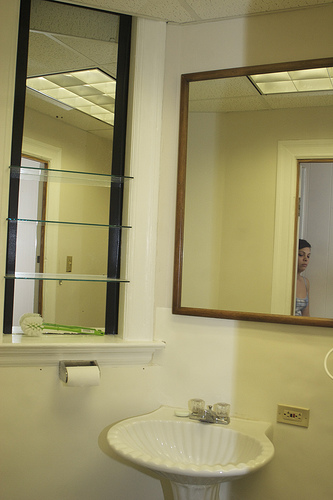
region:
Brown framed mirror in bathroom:
[171, 57, 332, 327]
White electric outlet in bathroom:
[275, 400, 311, 431]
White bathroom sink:
[104, 399, 272, 498]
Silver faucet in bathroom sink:
[199, 403, 218, 426]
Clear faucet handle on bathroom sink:
[215, 399, 232, 418]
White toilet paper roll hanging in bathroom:
[59, 362, 103, 388]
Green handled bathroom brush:
[15, 311, 106, 335]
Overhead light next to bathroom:
[26, 63, 115, 128]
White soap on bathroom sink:
[171, 403, 190, 420]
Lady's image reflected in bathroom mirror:
[291, 238, 313, 317]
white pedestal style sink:
[99, 396, 275, 499]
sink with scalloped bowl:
[102, 394, 275, 477]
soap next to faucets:
[173, 407, 191, 417]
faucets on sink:
[188, 398, 231, 427]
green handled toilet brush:
[20, 312, 103, 339]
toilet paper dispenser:
[55, 360, 104, 386]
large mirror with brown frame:
[177, 72, 331, 326]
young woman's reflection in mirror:
[295, 239, 313, 317]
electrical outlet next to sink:
[273, 400, 311, 429]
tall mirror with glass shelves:
[19, 2, 123, 331]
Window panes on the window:
[6, 164, 136, 288]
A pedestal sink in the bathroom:
[109, 406, 276, 497]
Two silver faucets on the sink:
[188, 395, 231, 424]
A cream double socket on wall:
[278, 403, 311, 427]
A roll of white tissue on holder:
[65, 366, 101, 385]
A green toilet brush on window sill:
[19, 313, 108, 337]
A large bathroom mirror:
[172, 66, 326, 325]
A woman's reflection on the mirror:
[297, 237, 312, 318]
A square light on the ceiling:
[26, 68, 114, 120]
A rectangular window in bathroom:
[2, 3, 127, 346]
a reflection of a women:
[288, 235, 318, 323]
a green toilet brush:
[13, 311, 115, 338]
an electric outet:
[271, 401, 316, 430]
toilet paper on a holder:
[57, 358, 116, 390]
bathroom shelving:
[7, 158, 134, 295]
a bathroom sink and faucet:
[104, 398, 277, 497]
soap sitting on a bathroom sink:
[171, 405, 192, 422]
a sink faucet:
[186, 395, 238, 427]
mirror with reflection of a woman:
[182, 74, 332, 324]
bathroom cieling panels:
[51, 0, 314, 23]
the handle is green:
[41, 313, 121, 336]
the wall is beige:
[205, 341, 281, 380]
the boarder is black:
[11, 53, 143, 351]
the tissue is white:
[43, 354, 117, 400]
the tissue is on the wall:
[40, 355, 120, 391]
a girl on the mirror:
[266, 215, 325, 339]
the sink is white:
[116, 391, 275, 498]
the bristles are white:
[19, 314, 60, 351]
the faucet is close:
[178, 383, 266, 435]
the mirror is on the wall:
[164, 207, 331, 386]